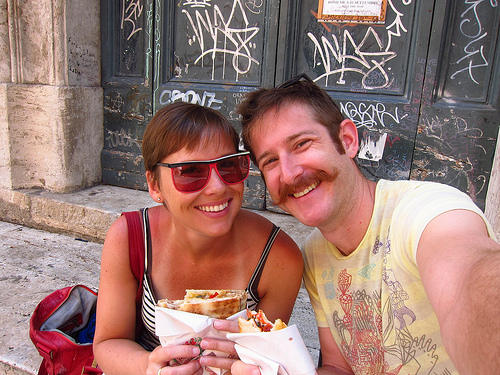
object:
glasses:
[153, 151, 251, 194]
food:
[156, 287, 286, 334]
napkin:
[156, 305, 252, 346]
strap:
[117, 210, 153, 281]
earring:
[157, 197, 161, 201]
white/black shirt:
[131, 202, 285, 343]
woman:
[92, 100, 300, 375]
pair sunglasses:
[274, 75, 318, 91]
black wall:
[101, 0, 500, 220]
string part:
[264, 240, 269, 266]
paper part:
[274, 351, 291, 361]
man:
[234, 72, 500, 375]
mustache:
[268, 169, 340, 206]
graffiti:
[101, 0, 490, 219]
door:
[151, 0, 280, 213]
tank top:
[137, 218, 284, 343]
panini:
[159, 286, 238, 319]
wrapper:
[170, 285, 238, 308]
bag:
[26, 283, 118, 375]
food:
[151, 289, 290, 333]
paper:
[225, 331, 320, 375]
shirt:
[297, 179, 497, 375]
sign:
[315, 0, 388, 25]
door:
[263, 0, 437, 218]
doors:
[96, 0, 152, 192]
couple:
[91, 70, 499, 375]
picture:
[0, 0, 500, 374]